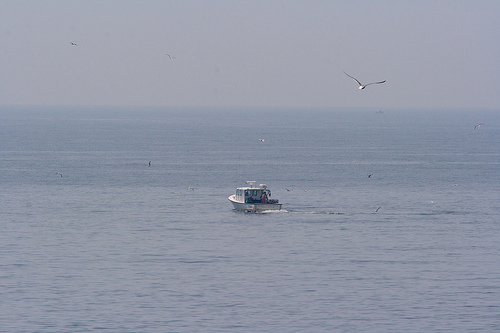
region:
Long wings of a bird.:
[343, 63, 391, 103]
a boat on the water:
[233, 151, 281, 242]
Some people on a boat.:
[261, 190, 270, 199]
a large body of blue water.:
[121, 108, 433, 308]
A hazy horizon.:
[96, 74, 416, 142]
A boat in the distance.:
[362, 102, 396, 120]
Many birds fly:
[138, 91, 454, 274]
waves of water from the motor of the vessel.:
[267, 208, 317, 219]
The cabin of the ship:
[233, 185, 257, 196]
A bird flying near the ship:
[277, 180, 297, 196]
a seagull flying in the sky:
[343, 69, 383, 94]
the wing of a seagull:
[338, 70, 358, 86]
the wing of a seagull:
[366, 76, 386, 87]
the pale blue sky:
[2, 2, 498, 113]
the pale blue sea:
[3, 111, 491, 331]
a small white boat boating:
[227, 183, 286, 213]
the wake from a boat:
[260, 206, 290, 216]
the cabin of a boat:
[235, 185, 264, 200]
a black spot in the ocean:
[145, 158, 155, 168]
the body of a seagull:
[357, 83, 364, 89]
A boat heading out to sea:
[205, 92, 409, 281]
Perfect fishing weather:
[38, 44, 477, 261]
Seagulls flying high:
[130, 48, 491, 277]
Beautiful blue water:
[19, 64, 499, 306]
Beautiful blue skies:
[24, 27, 494, 273]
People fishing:
[146, 104, 453, 253]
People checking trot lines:
[194, 171, 332, 226]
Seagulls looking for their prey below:
[34, 34, 493, 238]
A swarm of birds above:
[51, 16, 478, 241]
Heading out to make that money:
[36, 29, 491, 272]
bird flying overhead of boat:
[332, 69, 389, 93]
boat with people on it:
[217, 176, 276, 223]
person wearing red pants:
[255, 184, 270, 213]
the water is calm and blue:
[21, 174, 498, 324]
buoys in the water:
[144, 145, 381, 181]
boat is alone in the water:
[217, 174, 286, 225]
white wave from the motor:
[247, 205, 294, 222]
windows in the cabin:
[239, 186, 269, 204]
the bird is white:
[327, 69, 394, 110]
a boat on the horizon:
[352, 97, 408, 136]